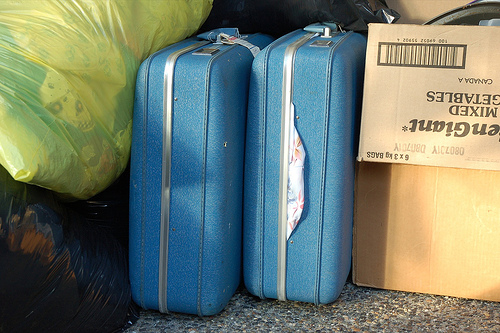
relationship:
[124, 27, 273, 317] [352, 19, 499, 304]
blue suitcase next to box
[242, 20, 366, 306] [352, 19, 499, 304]
blue suitcase next to box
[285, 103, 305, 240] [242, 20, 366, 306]
fabric sticking out of blue suitcase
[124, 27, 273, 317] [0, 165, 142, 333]
blue suitcase next to black bag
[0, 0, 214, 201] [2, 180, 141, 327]
bag on top of black bag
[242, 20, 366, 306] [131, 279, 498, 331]
blue suitcase on ground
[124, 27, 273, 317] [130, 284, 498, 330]
blue suitcase on ground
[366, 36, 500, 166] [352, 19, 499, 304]
writing on box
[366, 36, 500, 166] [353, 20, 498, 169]
writing on box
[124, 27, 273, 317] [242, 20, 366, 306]
blue suitcase next to blue suitcase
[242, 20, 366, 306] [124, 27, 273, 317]
blue suitcase next to blue suitcase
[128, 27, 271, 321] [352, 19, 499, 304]
blue suitcase next to box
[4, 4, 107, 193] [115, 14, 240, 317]
bag next to suitcase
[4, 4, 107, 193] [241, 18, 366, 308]
bag next to suitcase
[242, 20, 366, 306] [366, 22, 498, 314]
blue suitcase beside boxes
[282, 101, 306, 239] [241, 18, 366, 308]
fabric hanging out of suitcase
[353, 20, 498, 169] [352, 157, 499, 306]
box piled on box